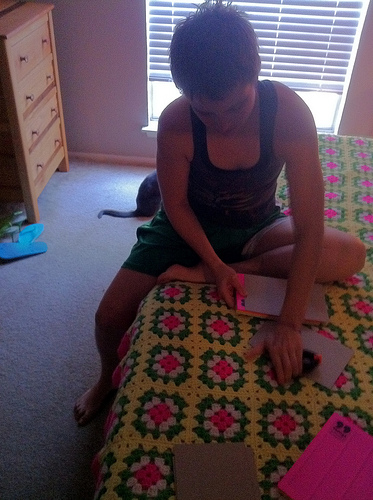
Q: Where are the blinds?
A: On the window.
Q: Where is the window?
A: Behind the boy.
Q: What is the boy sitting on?
A: A bed.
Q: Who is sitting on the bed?
A: The woman.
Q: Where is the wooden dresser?
A: To the left.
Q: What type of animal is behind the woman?
A: Cat.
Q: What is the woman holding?
A: Paper book.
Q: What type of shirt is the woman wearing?
A: Tank top.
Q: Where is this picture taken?
A: In woman's bedroom.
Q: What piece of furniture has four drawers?
A: A wooden dresser.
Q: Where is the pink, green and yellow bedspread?
A: On the bed.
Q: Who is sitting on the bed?
A: A boy.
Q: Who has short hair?
A: A boy.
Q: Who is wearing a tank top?
A: A boy.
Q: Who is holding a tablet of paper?
A: A boy.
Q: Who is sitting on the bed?
A: The boy.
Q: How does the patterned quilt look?
A: Pretty.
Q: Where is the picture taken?
A: A bedroom.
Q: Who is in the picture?
A: A woman.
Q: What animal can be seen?
A: A cat.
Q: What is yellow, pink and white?
A: Bedspread.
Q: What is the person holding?
A: Post it notes.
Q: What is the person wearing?
A: Tank top, shorts.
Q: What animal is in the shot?
A: Cat.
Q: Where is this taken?
A: Bed.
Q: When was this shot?
A: Daytime.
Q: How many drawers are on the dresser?
A: 4.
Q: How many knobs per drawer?
A: 2.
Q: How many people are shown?
A: 1.